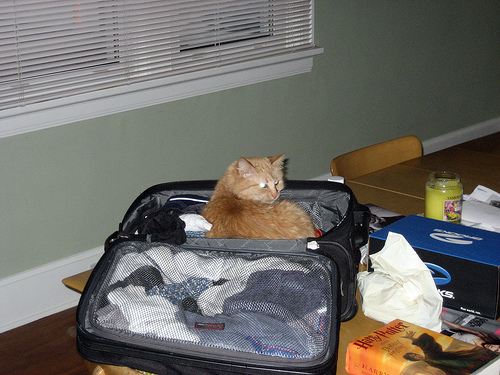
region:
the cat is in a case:
[192, 140, 314, 255]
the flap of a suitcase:
[85, 235, 330, 370]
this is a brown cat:
[204, 150, 324, 250]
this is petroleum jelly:
[405, 155, 480, 240]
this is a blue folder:
[367, 195, 492, 266]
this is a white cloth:
[360, 226, 446, 351]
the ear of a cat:
[228, 150, 248, 190]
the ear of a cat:
[268, 140, 289, 178]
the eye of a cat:
[260, 176, 271, 197]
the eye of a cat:
[273, 179, 300, 187]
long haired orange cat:
[213, 155, 319, 247]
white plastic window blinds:
[0, 2, 331, 137]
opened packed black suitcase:
[60, 233, 357, 372]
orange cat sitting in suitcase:
[67, 153, 372, 371]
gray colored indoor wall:
[208, 12, 476, 156]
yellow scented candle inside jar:
[423, 169, 469, 226]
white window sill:
[5, 42, 329, 137]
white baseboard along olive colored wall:
[1, 112, 498, 335]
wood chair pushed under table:
[329, 130, 434, 183]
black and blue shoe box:
[365, 212, 498, 321]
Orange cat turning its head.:
[193, 149, 325, 245]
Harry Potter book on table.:
[343, 305, 495, 374]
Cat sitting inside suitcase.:
[109, 154, 353, 259]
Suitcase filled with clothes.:
[82, 244, 347, 364]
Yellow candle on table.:
[427, 170, 462, 227]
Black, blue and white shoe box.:
[370, 215, 496, 307]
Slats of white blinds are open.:
[2, 3, 315, 84]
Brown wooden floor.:
[5, 327, 73, 372]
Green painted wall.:
[334, 39, 466, 126]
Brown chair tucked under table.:
[328, 131, 429, 189]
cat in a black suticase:
[81, 147, 365, 373]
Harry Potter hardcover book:
[344, 313, 498, 372]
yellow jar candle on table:
[420, 166, 467, 223]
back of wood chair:
[326, 137, 427, 176]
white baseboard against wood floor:
[412, 120, 497, 151]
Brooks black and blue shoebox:
[367, 204, 499, 311]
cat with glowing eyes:
[197, 152, 318, 238]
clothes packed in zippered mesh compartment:
[87, 233, 335, 365]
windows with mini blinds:
[3, 4, 331, 128]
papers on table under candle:
[451, 172, 496, 229]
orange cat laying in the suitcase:
[201, 153, 310, 247]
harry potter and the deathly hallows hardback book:
[348, 319, 498, 374]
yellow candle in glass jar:
[420, 165, 470, 225]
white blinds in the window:
[8, 5, 140, 85]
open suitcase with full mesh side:
[74, 235, 344, 372]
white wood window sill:
[154, 39, 337, 97]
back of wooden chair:
[319, 112, 439, 182]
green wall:
[329, 20, 451, 117]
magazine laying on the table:
[436, 300, 498, 352]